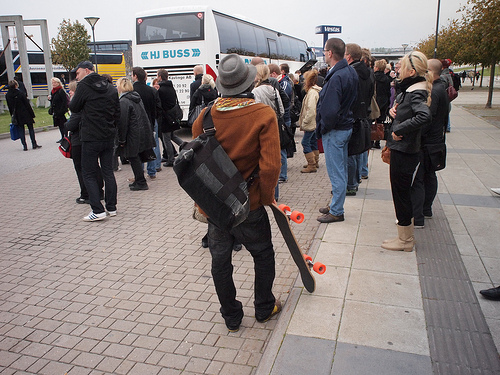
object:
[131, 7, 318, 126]
bus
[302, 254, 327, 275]
wheels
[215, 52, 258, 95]
cap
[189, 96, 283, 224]
coat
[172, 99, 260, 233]
bag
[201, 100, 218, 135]
strap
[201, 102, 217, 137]
shoulder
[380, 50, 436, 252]
lady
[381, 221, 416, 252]
boots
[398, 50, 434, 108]
hair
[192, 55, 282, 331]
man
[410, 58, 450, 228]
man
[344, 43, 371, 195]
man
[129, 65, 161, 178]
man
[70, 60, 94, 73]
hat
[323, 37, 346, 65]
head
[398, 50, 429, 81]
head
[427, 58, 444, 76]
head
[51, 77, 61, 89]
head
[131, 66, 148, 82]
head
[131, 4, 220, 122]
back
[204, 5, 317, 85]
side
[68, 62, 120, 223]
man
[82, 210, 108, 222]
sneaker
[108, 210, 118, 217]
sneaker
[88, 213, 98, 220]
stripes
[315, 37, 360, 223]
person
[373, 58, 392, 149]
person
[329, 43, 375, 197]
person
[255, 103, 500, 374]
sidewalk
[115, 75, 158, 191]
woman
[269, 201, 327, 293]
board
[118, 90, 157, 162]
jacket